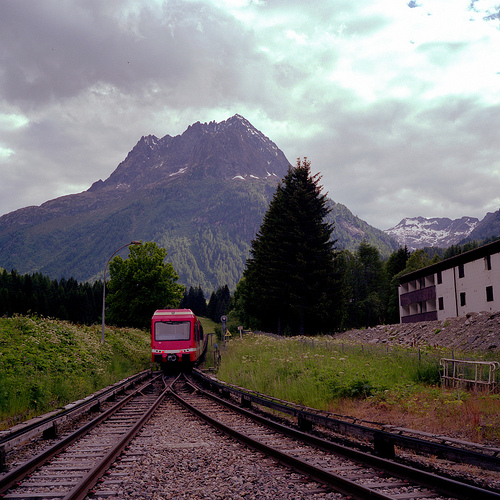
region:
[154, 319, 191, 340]
Windshield on a train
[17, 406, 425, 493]
Railroad tracks in the rocks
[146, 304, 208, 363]
A red train on the tracks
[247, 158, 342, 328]
A tall trees with dark leaves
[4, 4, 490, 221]
Heavy, gray clouds in the sky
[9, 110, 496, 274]
Mountain range in the distance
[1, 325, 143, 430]
Green grass next to the railroad tracks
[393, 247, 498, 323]
A white building on a small hill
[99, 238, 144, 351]
A lamp over the railroad tracks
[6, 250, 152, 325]
Trees leading to the woods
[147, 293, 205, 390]
a train on a train tracks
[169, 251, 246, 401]
a red train on the tracks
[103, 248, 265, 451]
a red train on a train tracks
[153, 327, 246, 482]
train tracks with train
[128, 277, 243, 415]
tracks with a red train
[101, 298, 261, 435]
train tracks with a red train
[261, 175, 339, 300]
leaves on a tall tree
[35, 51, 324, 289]
mountains covered in trees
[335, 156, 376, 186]
white clouds in blue sky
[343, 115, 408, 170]
white clouds in blue sky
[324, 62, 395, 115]
white clouds in blue sky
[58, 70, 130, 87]
white clouds in blue sky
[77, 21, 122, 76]
white clouds in blue sky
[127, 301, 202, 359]
red train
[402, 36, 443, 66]
white clouds in blue sky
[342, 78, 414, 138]
white clouds in blue sky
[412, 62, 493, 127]
white clouds in blue sky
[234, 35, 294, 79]
white clouds in blue sky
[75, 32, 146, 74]
white clouds in blue sky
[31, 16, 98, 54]
white clouds in blue sky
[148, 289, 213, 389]
red train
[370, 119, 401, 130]
white clouds in blue sky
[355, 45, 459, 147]
white clouds in blue sky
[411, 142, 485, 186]
white clouds in blue sky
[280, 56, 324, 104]
white clouds in blue sky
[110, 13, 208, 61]
white clouds in blue sky